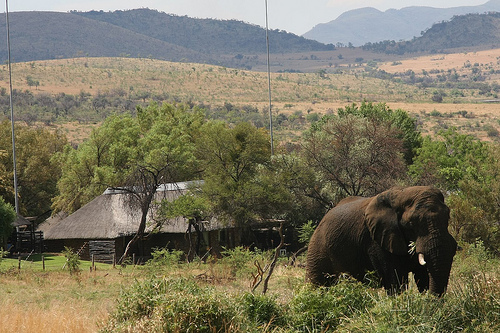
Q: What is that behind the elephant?
A: Trees in front of hut.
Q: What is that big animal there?
A: Elephant in field.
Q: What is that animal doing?
A: Elephant walking from hut.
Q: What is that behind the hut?
A: Mountain range.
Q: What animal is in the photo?
A: Elephant.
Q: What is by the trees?
A: House.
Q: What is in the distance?
A: Mountains.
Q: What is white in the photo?
A: Tusks.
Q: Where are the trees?
A: Behind elephant/.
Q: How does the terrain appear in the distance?
A: Hilly.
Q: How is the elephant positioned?
A: Standing.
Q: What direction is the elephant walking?
A: Right.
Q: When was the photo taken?
A: In the daytime.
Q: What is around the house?
A: Several trees.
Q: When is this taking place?
A: Daytime.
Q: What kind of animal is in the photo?
A: Elephant.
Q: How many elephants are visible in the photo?
A: One.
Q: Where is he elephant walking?
A: Grass.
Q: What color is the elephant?
A: Brown and grey.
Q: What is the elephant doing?
A: Eating.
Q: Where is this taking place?
A: In a wildlife refuge.